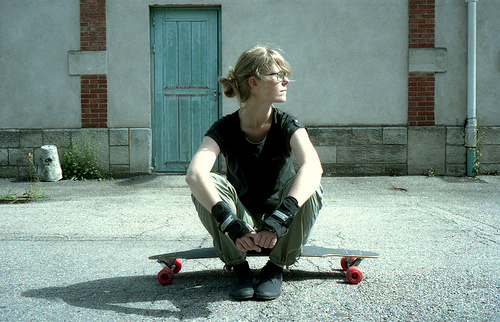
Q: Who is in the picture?
A: A woman.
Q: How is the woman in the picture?
A: Sitting.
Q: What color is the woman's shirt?
A: Black.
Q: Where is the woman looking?
A: To the left.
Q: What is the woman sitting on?
A: A skateboard.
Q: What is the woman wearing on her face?
A: Glasses.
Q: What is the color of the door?
A: Blue.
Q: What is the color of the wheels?
A: Red.